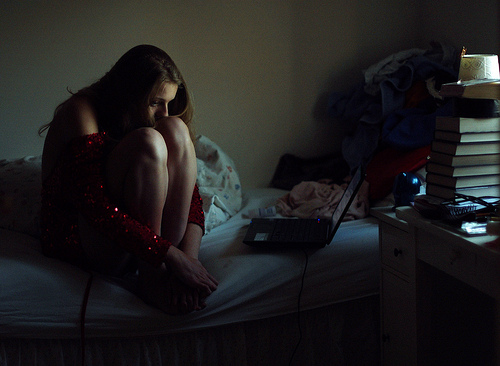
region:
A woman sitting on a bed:
[38, 45, 218, 316]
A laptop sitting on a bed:
[245, 164, 361, 249]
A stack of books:
[424, 80, 499, 217]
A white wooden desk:
[368, 203, 498, 365]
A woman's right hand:
[160, 244, 220, 294]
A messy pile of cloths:
[270, 34, 452, 217]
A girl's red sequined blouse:
[38, 133, 203, 262]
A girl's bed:
[0, 184, 384, 363]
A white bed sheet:
[0, 185, 374, 337]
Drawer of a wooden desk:
[375, 219, 417, 276]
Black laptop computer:
[242, 164, 365, 252]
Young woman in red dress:
[40, 43, 216, 313]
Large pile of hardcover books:
[425, 112, 497, 214]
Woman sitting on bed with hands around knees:
[41, 41, 216, 311]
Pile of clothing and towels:
[332, 47, 445, 167]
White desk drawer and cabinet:
[377, 210, 419, 363]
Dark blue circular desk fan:
[390, 169, 422, 212]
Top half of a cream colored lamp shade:
[460, 54, 496, 82]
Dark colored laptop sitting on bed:
[242, 163, 363, 248]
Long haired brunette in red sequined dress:
[41, 44, 217, 315]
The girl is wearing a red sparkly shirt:
[43, 32, 249, 304]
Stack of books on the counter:
[433, 102, 498, 207]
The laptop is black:
[230, 160, 365, 258]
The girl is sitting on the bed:
[38, 38, 241, 306]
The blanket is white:
[187, 127, 269, 224]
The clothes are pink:
[273, 163, 385, 228]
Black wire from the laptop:
[282, 242, 332, 354]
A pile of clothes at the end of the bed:
[318, 7, 448, 207]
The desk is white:
[366, 198, 494, 355]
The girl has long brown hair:
[83, 37, 199, 153]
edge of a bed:
[317, 277, 329, 292]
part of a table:
[398, 223, 418, 263]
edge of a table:
[388, 268, 415, 303]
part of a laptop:
[293, 215, 300, 229]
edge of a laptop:
[271, 221, 277, 240]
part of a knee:
[154, 148, 165, 160]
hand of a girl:
[174, 254, 190, 276]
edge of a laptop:
[343, 180, 360, 232]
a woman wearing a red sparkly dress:
[22, 28, 224, 316]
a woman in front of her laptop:
[34, 36, 374, 316]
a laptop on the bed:
[236, 160, 370, 259]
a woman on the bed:
[28, 38, 223, 326]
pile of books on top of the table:
[416, 102, 476, 198]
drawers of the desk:
[371, 225, 416, 364]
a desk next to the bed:
[348, 185, 474, 360]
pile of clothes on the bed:
[338, 32, 420, 161]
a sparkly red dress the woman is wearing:
[66, 186, 103, 256]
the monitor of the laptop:
[322, 160, 369, 254]